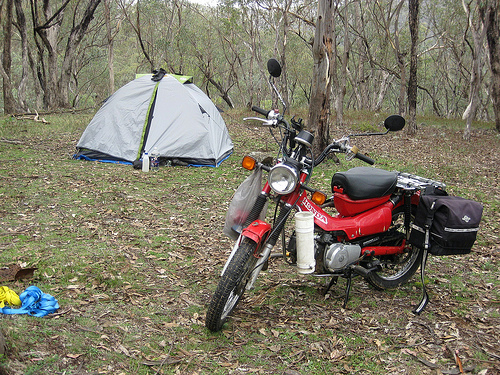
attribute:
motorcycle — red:
[196, 47, 484, 330]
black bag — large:
[418, 192, 481, 254]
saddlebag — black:
[413, 191, 481, 258]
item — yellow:
[0, 283, 22, 310]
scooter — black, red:
[204, 57, 481, 332]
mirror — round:
[348, 113, 405, 145]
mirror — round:
[266, 59, 283, 116]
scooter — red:
[209, 108, 439, 331]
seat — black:
[334, 171, 399, 195]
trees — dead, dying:
[7, 3, 114, 113]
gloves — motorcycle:
[146, 63, 168, 83]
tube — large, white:
[291, 207, 316, 276]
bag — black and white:
[409, 180, 496, 267]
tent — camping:
[74, 72, 244, 175]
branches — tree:
[3, 86, 78, 137]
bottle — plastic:
[131, 145, 151, 172]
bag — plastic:
[226, 172, 301, 224]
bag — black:
[414, 193, 481, 261]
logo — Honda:
[300, 194, 330, 226]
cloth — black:
[150, 67, 166, 82]